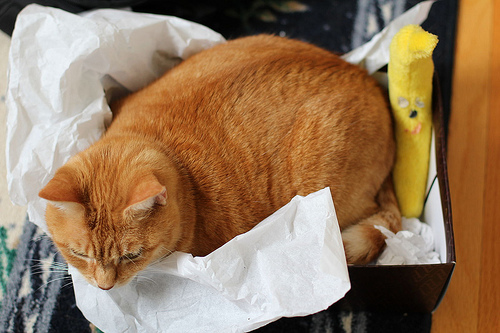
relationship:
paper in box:
[5, 3, 352, 331] [327, 63, 456, 312]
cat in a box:
[33, 29, 408, 296] [38, 56, 471, 308]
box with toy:
[38, 56, 471, 308] [372, 18, 450, 225]